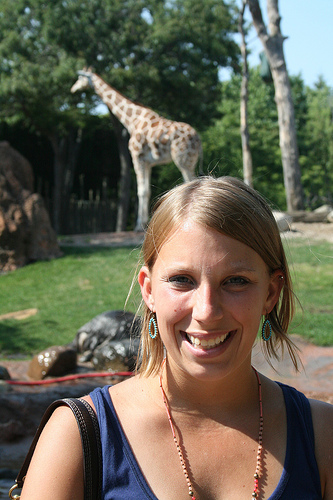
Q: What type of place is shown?
A: It is a zoo.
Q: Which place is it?
A: It is a zoo.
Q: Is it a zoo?
A: Yes, it is a zoo.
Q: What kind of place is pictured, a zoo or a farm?
A: It is a zoo.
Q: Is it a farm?
A: No, it is a zoo.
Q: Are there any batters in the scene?
A: No, there are no batters.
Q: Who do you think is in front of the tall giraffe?
A: The girl is in front of the giraffe.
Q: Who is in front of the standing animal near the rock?
A: The girl is in front of the giraffe.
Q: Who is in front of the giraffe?
A: The girl is in front of the giraffe.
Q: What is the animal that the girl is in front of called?
A: The animal is a giraffe.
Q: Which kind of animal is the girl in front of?
A: The girl is in front of the giraffe.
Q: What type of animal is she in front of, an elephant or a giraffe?
A: The girl is in front of a giraffe.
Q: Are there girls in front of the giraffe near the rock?
A: Yes, there is a girl in front of the giraffe.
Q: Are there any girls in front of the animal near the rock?
A: Yes, there is a girl in front of the giraffe.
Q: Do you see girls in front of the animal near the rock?
A: Yes, there is a girl in front of the giraffe.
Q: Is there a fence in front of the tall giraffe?
A: No, there is a girl in front of the giraffe.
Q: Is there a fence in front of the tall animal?
A: No, there is a girl in front of the giraffe.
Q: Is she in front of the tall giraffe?
A: Yes, the girl is in front of the giraffe.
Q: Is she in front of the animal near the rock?
A: Yes, the girl is in front of the giraffe.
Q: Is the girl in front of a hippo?
A: No, the girl is in front of the giraffe.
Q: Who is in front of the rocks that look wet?
A: The girl is in front of the rocks.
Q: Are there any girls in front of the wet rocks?
A: Yes, there is a girl in front of the rocks.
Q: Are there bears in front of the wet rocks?
A: No, there is a girl in front of the rocks.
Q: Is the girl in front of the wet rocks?
A: Yes, the girl is in front of the rocks.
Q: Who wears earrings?
A: The girl wears earrings.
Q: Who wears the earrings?
A: The girl wears earrings.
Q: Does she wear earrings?
A: Yes, the girl wears earrings.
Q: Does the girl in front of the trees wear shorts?
A: No, the girl wears earrings.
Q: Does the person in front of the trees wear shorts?
A: No, the girl wears earrings.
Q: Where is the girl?
A: The girl is at the zoo.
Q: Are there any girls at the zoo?
A: Yes, there is a girl at the zoo.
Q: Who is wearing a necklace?
A: The girl is wearing a necklace.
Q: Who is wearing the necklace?
A: The girl is wearing a necklace.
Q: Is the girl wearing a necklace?
A: Yes, the girl is wearing a necklace.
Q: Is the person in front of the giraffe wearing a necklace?
A: Yes, the girl is wearing a necklace.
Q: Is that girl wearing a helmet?
A: No, the girl is wearing a necklace.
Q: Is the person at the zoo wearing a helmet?
A: No, the girl is wearing a necklace.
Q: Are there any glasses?
A: No, there are no glasses.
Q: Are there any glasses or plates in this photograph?
A: No, there are no glasses or plates.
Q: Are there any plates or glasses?
A: No, there are no glasses or plates.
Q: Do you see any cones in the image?
A: No, there are no cones.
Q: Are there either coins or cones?
A: No, there are no cones or coins.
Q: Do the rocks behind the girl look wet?
A: Yes, the rocks are wet.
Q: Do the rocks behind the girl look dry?
A: No, the rocks are wet.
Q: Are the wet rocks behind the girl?
A: Yes, the rocks are behind the girl.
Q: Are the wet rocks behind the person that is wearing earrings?
A: Yes, the rocks are behind the girl.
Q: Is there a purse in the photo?
A: Yes, there is a purse.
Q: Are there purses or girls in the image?
A: Yes, there is a purse.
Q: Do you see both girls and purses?
A: Yes, there are both a purse and a girl.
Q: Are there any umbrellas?
A: No, there are no umbrellas.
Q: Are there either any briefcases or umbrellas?
A: No, there are no umbrellas or briefcases.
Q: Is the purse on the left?
A: Yes, the purse is on the left of the image.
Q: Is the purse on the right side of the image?
A: No, the purse is on the left of the image.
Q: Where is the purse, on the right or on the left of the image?
A: The purse is on the left of the image.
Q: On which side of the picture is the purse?
A: The purse is on the left of the image.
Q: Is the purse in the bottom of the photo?
A: Yes, the purse is in the bottom of the image.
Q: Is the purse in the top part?
A: No, the purse is in the bottom of the image.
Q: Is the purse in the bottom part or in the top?
A: The purse is in the bottom of the image.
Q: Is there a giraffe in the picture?
A: Yes, there is a giraffe.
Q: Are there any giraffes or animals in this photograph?
A: Yes, there is a giraffe.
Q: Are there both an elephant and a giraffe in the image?
A: No, there is a giraffe but no elephants.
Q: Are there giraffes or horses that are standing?
A: Yes, the giraffe is standing.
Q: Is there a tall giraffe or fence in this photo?
A: Yes, there is a tall giraffe.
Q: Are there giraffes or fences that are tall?
A: Yes, the giraffe is tall.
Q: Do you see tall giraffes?
A: Yes, there is a tall giraffe.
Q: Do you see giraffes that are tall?
A: Yes, there is a tall giraffe.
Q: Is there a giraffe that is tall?
A: Yes, there is a giraffe that is tall.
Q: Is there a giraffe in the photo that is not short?
A: Yes, there is a tall giraffe.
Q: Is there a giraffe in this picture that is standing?
A: Yes, there is a giraffe that is standing.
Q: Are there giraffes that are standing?
A: Yes, there is a giraffe that is standing.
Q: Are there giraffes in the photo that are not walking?
A: Yes, there is a giraffe that is standing.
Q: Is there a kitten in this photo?
A: No, there are no kittens.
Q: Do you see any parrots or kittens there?
A: No, there are no kittens or parrots.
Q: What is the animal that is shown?
A: The animal is a giraffe.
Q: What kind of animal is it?
A: The animal is a giraffe.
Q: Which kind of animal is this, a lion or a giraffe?
A: This is a giraffe.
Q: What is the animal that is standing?
A: The animal is a giraffe.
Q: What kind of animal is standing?
A: The animal is a giraffe.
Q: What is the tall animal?
A: The animal is a giraffe.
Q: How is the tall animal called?
A: The animal is a giraffe.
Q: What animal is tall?
A: The animal is a giraffe.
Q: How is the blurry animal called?
A: The animal is a giraffe.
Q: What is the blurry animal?
A: The animal is a giraffe.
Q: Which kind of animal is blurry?
A: The animal is a giraffe.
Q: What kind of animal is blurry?
A: The animal is a giraffe.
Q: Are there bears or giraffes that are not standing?
A: No, there is a giraffe but it is standing.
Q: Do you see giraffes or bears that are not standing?
A: No, there is a giraffe but it is standing.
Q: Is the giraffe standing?
A: Yes, the giraffe is standing.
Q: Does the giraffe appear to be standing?
A: Yes, the giraffe is standing.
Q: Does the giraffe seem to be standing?
A: Yes, the giraffe is standing.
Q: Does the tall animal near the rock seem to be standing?
A: Yes, the giraffe is standing.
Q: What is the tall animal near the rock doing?
A: The giraffe is standing.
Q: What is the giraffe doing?
A: The giraffe is standing.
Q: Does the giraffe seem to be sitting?
A: No, the giraffe is standing.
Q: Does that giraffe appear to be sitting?
A: No, the giraffe is standing.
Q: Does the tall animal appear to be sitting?
A: No, the giraffe is standing.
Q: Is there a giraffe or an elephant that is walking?
A: No, there is a giraffe but it is standing.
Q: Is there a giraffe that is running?
A: No, there is a giraffe but it is standing.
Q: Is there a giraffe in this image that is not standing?
A: No, there is a giraffe but it is standing.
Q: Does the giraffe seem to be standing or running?
A: The giraffe is standing.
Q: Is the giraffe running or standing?
A: The giraffe is standing.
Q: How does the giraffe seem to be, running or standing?
A: The giraffe is standing.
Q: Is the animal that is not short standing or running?
A: The giraffe is standing.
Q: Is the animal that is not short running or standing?
A: The giraffe is standing.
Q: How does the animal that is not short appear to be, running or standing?
A: The giraffe is standing.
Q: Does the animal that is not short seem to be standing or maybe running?
A: The giraffe is standing.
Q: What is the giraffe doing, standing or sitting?
A: The giraffe is standing.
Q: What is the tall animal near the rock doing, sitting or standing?
A: The giraffe is standing.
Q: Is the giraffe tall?
A: Yes, the giraffe is tall.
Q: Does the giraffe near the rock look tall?
A: Yes, the giraffe is tall.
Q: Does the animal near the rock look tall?
A: Yes, the giraffe is tall.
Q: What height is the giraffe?
A: The giraffe is tall.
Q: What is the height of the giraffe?
A: The giraffe is tall.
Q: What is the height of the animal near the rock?
A: The giraffe is tall.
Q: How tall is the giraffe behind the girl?
A: The giraffe is tall.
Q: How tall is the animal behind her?
A: The giraffe is tall.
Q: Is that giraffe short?
A: No, the giraffe is tall.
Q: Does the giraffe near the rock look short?
A: No, the giraffe is tall.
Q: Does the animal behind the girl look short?
A: No, the giraffe is tall.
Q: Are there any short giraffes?
A: No, there is a giraffe but it is tall.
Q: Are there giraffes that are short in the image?
A: No, there is a giraffe but it is tall.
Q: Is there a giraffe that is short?
A: No, there is a giraffe but it is tall.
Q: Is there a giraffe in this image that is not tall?
A: No, there is a giraffe but it is tall.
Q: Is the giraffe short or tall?
A: The giraffe is tall.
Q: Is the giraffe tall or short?
A: The giraffe is tall.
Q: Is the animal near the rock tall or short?
A: The giraffe is tall.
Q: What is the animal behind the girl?
A: The animal is a giraffe.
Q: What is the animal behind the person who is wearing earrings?
A: The animal is a giraffe.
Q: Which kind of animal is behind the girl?
A: The animal is a giraffe.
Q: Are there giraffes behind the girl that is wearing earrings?
A: Yes, there is a giraffe behind the girl.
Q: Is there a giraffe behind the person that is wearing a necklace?
A: Yes, there is a giraffe behind the girl.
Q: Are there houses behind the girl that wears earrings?
A: No, there is a giraffe behind the girl.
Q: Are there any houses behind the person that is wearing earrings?
A: No, there is a giraffe behind the girl.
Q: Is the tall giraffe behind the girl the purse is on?
A: Yes, the giraffe is behind the girl.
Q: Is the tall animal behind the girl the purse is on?
A: Yes, the giraffe is behind the girl.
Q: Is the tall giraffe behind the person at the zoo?
A: Yes, the giraffe is behind the girl.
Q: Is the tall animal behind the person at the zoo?
A: Yes, the giraffe is behind the girl.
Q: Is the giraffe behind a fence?
A: No, the giraffe is behind the girl.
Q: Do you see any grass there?
A: Yes, there is grass.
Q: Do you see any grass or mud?
A: Yes, there is grass.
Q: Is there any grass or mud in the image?
A: Yes, there is grass.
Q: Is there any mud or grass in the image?
A: Yes, there is grass.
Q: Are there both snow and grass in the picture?
A: No, there is grass but no snow.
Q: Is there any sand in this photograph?
A: No, there is no sand.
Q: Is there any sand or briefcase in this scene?
A: No, there are no sand or briefcases.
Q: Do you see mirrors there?
A: No, there are no mirrors.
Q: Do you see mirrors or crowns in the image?
A: No, there are no mirrors or crowns.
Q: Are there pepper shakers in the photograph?
A: No, there are no pepper shakers.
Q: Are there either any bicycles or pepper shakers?
A: No, there are no pepper shakers or bicycles.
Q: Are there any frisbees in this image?
A: No, there are no frisbees.